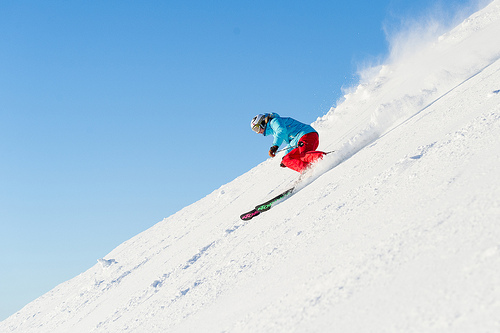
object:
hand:
[266, 145, 280, 158]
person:
[247, 110, 327, 173]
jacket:
[260, 111, 318, 159]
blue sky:
[0, 0, 492, 319]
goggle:
[249, 114, 271, 135]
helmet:
[247, 111, 271, 133]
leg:
[279, 146, 307, 175]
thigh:
[296, 136, 321, 155]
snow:
[0, 0, 499, 332]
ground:
[0, 0, 499, 332]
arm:
[265, 119, 287, 149]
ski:
[254, 188, 297, 213]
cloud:
[0, 0, 492, 320]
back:
[277, 116, 316, 133]